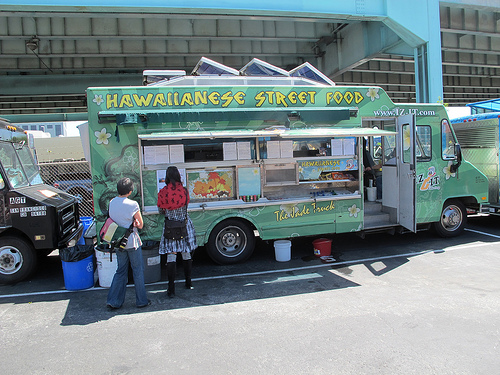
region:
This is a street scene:
[2, 0, 497, 370]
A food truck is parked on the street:
[84, 54, 492, 264]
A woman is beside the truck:
[154, 162, 198, 299]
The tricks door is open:
[357, 112, 419, 234]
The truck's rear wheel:
[206, 215, 256, 265]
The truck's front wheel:
[437, 198, 468, 239]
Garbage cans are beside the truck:
[57, 235, 162, 293]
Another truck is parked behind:
[0, 114, 82, 287]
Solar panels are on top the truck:
[191, 55, 334, 85]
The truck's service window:
[136, 128, 363, 215]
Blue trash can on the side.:
[55, 248, 93, 295]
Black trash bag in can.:
[57, 233, 101, 261]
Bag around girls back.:
[94, 222, 134, 253]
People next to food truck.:
[105, 156, 209, 301]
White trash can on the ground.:
[100, 238, 134, 295]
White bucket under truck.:
[278, 228, 300, 263]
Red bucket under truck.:
[308, 225, 346, 269]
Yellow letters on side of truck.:
[94, 91, 389, 116]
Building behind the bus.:
[20, 9, 422, 76]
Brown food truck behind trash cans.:
[0, 98, 71, 283]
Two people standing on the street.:
[87, 152, 218, 322]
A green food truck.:
[77, 74, 491, 263]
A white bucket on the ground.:
[267, 240, 297, 266]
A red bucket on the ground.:
[305, 234, 338, 266]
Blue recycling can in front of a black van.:
[2, 113, 99, 300]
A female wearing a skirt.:
[149, 162, 202, 302]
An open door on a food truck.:
[352, 106, 430, 237]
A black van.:
[2, 113, 84, 292]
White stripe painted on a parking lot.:
[1, 215, 497, 315]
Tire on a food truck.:
[204, 208, 263, 270]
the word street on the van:
[256, 89, 316, 108]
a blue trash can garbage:
[65, 249, 91, 286]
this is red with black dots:
[158, 185, 188, 207]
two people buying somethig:
[103, 174, 190, 313]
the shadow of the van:
[68, 233, 486, 323]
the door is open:
[360, 116, 418, 237]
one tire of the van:
[208, 219, 254, 263]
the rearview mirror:
[452, 145, 460, 172]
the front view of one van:
[0, 118, 80, 245]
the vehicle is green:
[86, 85, 491, 262]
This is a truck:
[99, 77, 446, 223]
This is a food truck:
[74, 56, 414, 230]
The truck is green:
[107, 102, 231, 200]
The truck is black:
[2, 161, 104, 263]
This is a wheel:
[212, 216, 329, 302]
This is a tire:
[213, 230, 276, 275]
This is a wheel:
[228, 241, 234, 258]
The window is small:
[349, 133, 497, 184]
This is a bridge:
[292, 16, 342, 67]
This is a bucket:
[254, 229, 300, 271]